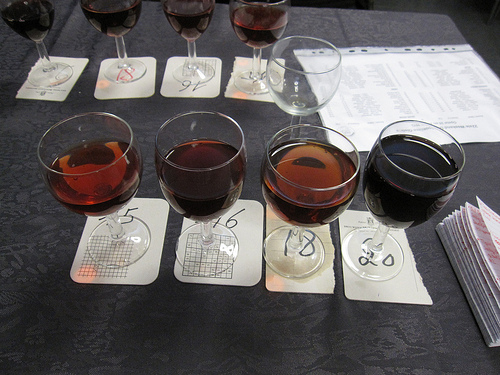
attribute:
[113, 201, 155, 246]
number —   5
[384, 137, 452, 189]
wine — red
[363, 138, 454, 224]
red wine — dark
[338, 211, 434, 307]
place holder — paper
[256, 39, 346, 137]
glass — clear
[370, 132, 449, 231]
wine — red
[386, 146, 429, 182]
liquid — black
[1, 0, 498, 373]
table — black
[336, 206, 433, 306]
coaster — white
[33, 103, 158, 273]
glass — red, empty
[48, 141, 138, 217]
wine — light red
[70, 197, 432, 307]
coasters — white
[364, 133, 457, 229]
liquid — dark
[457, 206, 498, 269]
notes — red